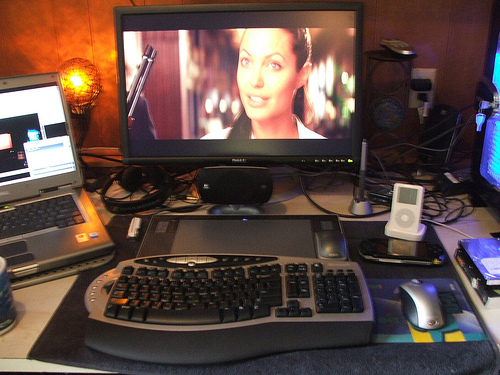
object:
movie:
[122, 14, 353, 157]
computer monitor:
[111, 2, 365, 167]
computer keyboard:
[77, 250, 376, 368]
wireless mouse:
[397, 278, 448, 332]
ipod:
[388, 182, 426, 234]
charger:
[384, 219, 429, 241]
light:
[58, 57, 103, 107]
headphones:
[99, 163, 179, 215]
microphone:
[348, 113, 376, 217]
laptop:
[0, 70, 118, 287]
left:
[0, 0, 73, 375]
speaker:
[194, 164, 274, 215]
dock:
[384, 220, 427, 242]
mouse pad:
[377, 278, 398, 344]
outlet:
[408, 67, 438, 109]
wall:
[424, 2, 475, 59]